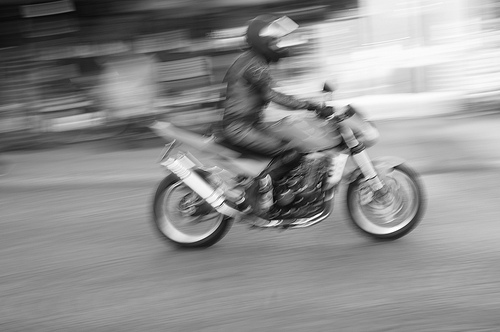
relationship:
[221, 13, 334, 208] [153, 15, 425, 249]
man on a bike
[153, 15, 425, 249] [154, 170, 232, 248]
bike has a wheel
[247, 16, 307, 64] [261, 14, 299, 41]
helmet has a visor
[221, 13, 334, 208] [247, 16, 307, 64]
man has on a helmet